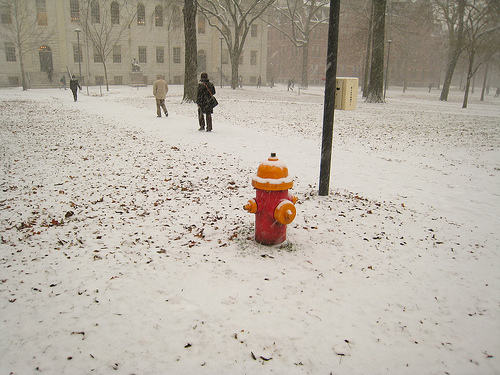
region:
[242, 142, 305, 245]
Fire hydrant in the snow.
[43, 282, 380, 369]
Snow on the ground.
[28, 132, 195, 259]
Leaves in the snow.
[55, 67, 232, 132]
People walking in the snow.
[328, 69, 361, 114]
Box on the pole.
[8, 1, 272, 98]
Building in the background.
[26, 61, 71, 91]
Steps on the building.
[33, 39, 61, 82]
The door is arched.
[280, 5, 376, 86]
The building is brick.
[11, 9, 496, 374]
Taken when it was snowing.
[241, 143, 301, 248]
a red and yellow fire hydrant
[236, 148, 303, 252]
a fire hydrant covered in snow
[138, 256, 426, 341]
a patch white snow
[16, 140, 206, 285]
a patch of leafs and snow mixed together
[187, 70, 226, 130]
a man carrying a bag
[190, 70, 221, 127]
a man walking in the snow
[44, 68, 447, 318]
snow coming down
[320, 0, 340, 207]
a light pole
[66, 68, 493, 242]
a walk way for people coved in snow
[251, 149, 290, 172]
the top of a fire hydrant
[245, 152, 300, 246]
a red and yellow fire hyrdant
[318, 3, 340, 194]
the thin trunk of a tree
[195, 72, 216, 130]
back of a person walking in snow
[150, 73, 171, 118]
back of a person walking in snow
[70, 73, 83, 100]
back of a person walking in snow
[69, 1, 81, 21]
exterior window on a building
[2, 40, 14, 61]
exterior window on a building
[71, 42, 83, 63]
exterior window on a building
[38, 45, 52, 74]
entryway for a building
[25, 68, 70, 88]
stairs leading to a door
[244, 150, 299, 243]
a fire hydrant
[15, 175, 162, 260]
leaves on the ground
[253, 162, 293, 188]
top of the fire hydrant is orange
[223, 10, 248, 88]
a tree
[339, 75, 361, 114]
a white trash can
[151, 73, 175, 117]
a person standing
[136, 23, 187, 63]
a building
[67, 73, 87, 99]
a person walking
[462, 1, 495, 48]
teh tree branches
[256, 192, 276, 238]
the fire hydrant is red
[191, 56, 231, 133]
a person wearing black walking in snow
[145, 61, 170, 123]
a person with a beige jacket walking in snow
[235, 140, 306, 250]
a fire hydrant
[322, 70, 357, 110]
an electrical power source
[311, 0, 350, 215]
a large pole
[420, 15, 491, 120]
some trees with no leaves on them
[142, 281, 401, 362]
some fresh snow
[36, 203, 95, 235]
some leaves cover by snow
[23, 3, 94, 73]
a large building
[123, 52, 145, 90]
a statue